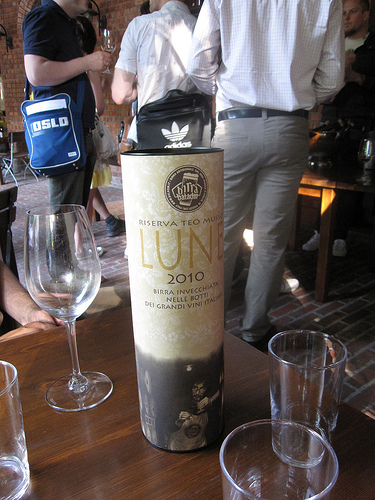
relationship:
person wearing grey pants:
[186, 0, 344, 349] [207, 105, 310, 345]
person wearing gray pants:
[186, 0, 344, 349] [212, 114, 312, 352]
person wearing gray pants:
[198, 4, 314, 349] [212, 114, 312, 348]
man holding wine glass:
[19, 1, 106, 288] [96, 27, 120, 75]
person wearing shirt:
[186, 0, 344, 349] [180, 3, 358, 125]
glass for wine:
[28, 194, 82, 269] [118, 147, 227, 453]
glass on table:
[266, 327, 351, 466] [14, 409, 153, 498]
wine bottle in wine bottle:
[120, 147, 224, 451] [120, 147, 224, 451]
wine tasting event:
[112, 121, 236, 498] [22, 0, 364, 167]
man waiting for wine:
[19, 1, 106, 288] [118, 147, 227, 453]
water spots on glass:
[54, 235, 82, 274] [21, 201, 114, 413]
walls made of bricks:
[1, 0, 23, 108] [3, 39, 19, 132]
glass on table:
[21, 201, 114, 413] [0, 301, 373, 498]